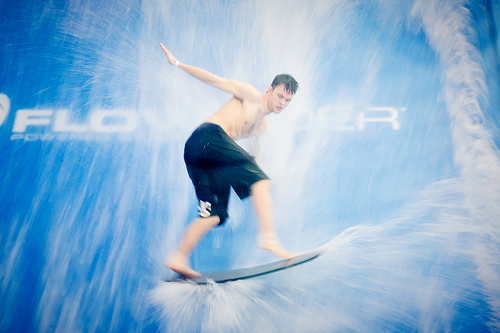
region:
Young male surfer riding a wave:
[157, 37, 326, 285]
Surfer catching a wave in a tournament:
[157, 38, 328, 293]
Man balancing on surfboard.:
[158, 43, 323, 288]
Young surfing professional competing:
[157, 40, 326, 288]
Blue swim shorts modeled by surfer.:
[166, 121, 323, 286]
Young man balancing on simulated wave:
[161, 39, 329, 287]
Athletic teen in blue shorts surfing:
[159, 40, 329, 288]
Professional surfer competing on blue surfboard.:
[154, 26, 321, 288]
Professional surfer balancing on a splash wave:
[157, 40, 327, 279]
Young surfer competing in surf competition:
[157, 38, 325, 286]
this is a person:
[134, 0, 309, 280]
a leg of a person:
[219, 109, 296, 276]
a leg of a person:
[142, 127, 232, 290]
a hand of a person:
[143, 33, 243, 105]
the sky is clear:
[34, 50, 119, 163]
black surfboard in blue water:
[157, 245, 323, 290]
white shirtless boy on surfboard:
[161, 35, 308, 277]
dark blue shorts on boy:
[184, 116, 262, 221]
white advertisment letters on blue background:
[0, 88, 408, 141]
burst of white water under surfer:
[0, 0, 498, 330]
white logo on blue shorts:
[195, 199, 212, 218]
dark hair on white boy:
[271, 73, 298, 91]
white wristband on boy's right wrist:
[172, 58, 180, 68]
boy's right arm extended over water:
[157, 41, 261, 93]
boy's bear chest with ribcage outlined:
[212, 87, 270, 136]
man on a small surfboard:
[137, 40, 332, 298]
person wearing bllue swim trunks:
[162, 120, 269, 235]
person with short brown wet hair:
[247, 65, 304, 125]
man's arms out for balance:
[133, 38, 335, 273]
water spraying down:
[29, 8, 349, 288]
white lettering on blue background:
[14, 70, 416, 152]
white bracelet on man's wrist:
[162, 54, 188, 78]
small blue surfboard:
[158, 239, 346, 286]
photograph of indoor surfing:
[31, 24, 470, 304]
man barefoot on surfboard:
[140, 235, 318, 292]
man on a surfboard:
[120, 30, 359, 296]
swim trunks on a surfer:
[168, 122, 283, 220]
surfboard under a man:
[163, 250, 327, 293]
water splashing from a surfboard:
[328, 211, 474, 325]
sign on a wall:
[15, 87, 431, 149]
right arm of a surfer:
[156, 41, 250, 108]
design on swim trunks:
[190, 190, 220, 223]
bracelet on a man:
[165, 53, 185, 73]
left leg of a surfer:
[163, 193, 220, 298]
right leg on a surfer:
[248, 178, 303, 270]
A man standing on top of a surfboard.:
[162, 41, 326, 291]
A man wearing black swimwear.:
[140, 49, 337, 289]